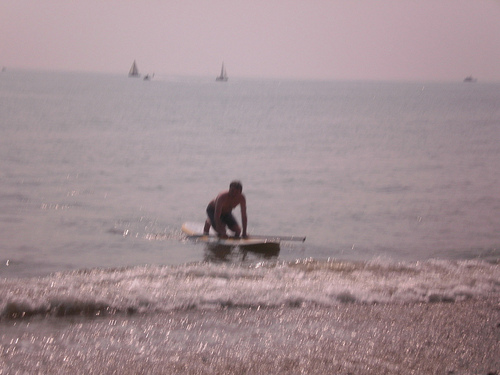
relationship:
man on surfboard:
[201, 178, 249, 240] [180, 221, 280, 252]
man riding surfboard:
[201, 178, 249, 240] [172, 220, 295, 257]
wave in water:
[9, 260, 498, 317] [1, 77, 498, 319]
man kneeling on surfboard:
[189, 178, 267, 258] [167, 217, 294, 269]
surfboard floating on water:
[175, 214, 283, 254] [0, 67, 498, 278]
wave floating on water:
[0, 260, 498, 318] [0, 0, 497, 372]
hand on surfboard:
[239, 229, 249, 241] [182, 217, 283, 249]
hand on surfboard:
[214, 232, 226, 242] [182, 217, 283, 249]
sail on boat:
[126, 60, 134, 75] [127, 55, 142, 80]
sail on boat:
[128, 57, 141, 75] [127, 55, 142, 80]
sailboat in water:
[126, 60, 145, 79] [1, 68, 498, 361]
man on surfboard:
[201, 178, 249, 240] [181, 217, 287, 254]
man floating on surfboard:
[201, 178, 249, 240] [182, 216, 309, 248]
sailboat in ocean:
[126, 60, 143, 78] [3, 76, 498, 187]